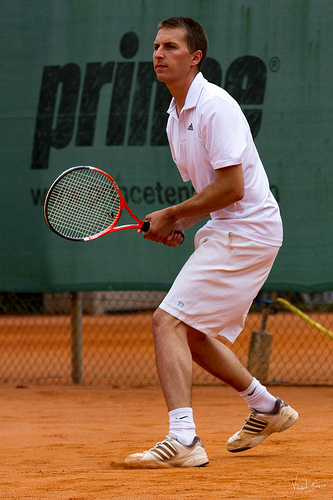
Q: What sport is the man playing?
A: Tennis.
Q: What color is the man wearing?
A: White.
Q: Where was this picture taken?
A: Tennis court.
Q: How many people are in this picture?
A: 1.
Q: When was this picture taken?
A: Daytime.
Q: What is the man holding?
A: Tennis racket.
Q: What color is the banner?
A: Green.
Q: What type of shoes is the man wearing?
A: Sneakers.